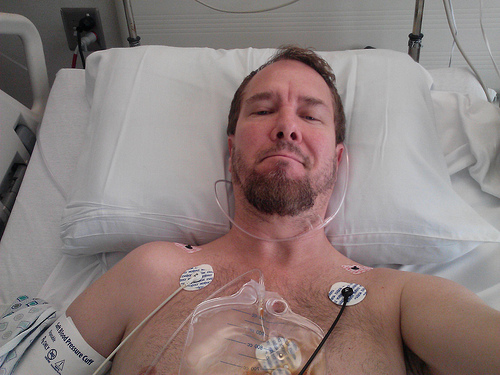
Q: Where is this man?
A: The hospital.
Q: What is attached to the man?
A: Monitors.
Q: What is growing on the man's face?
A: A beard.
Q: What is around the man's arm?
A: Blood pressure cuff.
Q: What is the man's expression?
A: Content.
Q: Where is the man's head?
A: A pillow.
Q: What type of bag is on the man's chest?
A: Urine.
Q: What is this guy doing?
A: Laying down.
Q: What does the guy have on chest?
A: Medical iv bag.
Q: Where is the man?
A: In the hospital.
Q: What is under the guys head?
A: Pillow.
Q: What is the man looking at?
A: Camera.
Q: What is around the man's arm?
A: BP cuff.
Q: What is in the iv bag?
A: Liquid.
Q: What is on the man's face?
A: Beard.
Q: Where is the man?
A: Hospital.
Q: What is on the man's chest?
A: Tube.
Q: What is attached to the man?
A: Wire.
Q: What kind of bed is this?
A: Hospital bed.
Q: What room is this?
A: Hospital room.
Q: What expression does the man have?
A: Unhappy.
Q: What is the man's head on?
A: Pillow.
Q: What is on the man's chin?
A: Beard.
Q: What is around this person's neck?
A: A tube.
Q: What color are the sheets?
A: White.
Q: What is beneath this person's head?
A: A pillow.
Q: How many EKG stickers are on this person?
A: Five.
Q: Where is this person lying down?
A: In a bed.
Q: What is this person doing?
A: Laying down.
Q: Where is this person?
A: In a hospital.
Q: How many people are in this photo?
A: One.